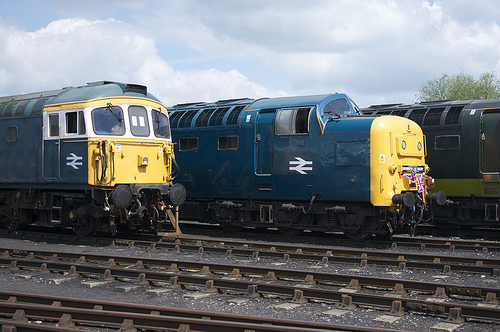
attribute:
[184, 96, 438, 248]
engines — yellow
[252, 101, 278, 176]
door — shut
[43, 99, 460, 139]
windows — one, open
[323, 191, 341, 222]
ground — yellow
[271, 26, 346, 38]
sky — cloudy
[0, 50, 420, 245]
trains — blue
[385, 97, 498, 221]
train — green, dark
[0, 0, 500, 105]
clouds — white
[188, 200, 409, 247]
bottom — part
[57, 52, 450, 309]
trains — three, different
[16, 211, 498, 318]
tracks — MANY  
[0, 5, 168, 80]
cloud — white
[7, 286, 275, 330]
rail lines — brown, shiny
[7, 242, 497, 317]
rail lines — brown, shiny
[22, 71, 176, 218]
train — blue, yellow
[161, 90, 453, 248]
train — blue, yellow, another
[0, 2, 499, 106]
sky — blue